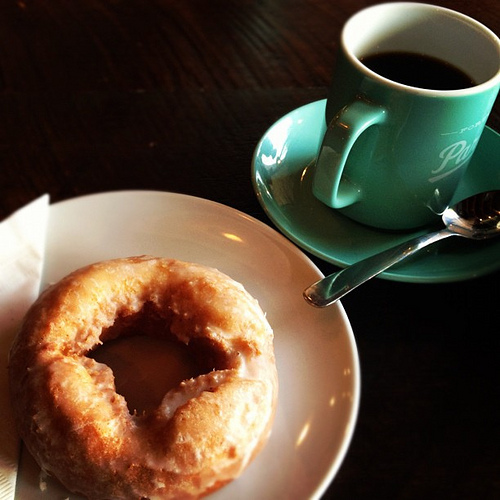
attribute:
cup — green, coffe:
[324, 9, 483, 273]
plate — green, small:
[245, 81, 483, 318]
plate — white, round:
[5, 164, 383, 496]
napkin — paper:
[2, 173, 49, 496]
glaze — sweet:
[157, 257, 288, 448]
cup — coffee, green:
[302, 11, 483, 269]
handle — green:
[309, 75, 399, 246]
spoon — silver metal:
[305, 175, 483, 359]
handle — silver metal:
[305, 215, 470, 341]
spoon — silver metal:
[292, 173, 483, 304]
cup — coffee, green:
[286, 7, 484, 263]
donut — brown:
[7, 237, 332, 487]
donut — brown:
[19, 233, 279, 490]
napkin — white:
[5, 169, 59, 496]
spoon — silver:
[297, 194, 484, 351]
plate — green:
[239, 66, 483, 311]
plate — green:
[244, 67, 483, 345]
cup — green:
[298, 9, 484, 249]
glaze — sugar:
[159, 257, 293, 461]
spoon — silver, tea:
[306, 186, 496, 306]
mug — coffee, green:
[339, 0, 497, 230]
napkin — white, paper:
[7, 189, 53, 499]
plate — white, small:
[4, 189, 363, 498]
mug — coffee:
[315, 3, 497, 232]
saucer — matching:
[251, 90, 494, 283]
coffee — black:
[383, 47, 455, 89]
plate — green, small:
[251, 92, 496, 286]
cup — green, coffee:
[323, 0, 497, 239]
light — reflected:
[221, 229, 248, 245]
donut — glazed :
[8, 257, 273, 498]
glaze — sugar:
[221, 400, 259, 449]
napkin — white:
[0, 189, 55, 496]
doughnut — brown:
[17, 256, 281, 490]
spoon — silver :
[300, 184, 498, 274]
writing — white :
[434, 135, 464, 179]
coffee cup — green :
[310, 5, 495, 235]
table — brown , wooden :
[57, 5, 224, 155]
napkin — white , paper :
[0, 188, 40, 498]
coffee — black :
[371, 43, 471, 100]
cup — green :
[310, 4, 496, 225]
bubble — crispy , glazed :
[190, 370, 241, 418]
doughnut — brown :
[30, 257, 260, 499]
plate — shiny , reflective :
[11, 186, 327, 492]